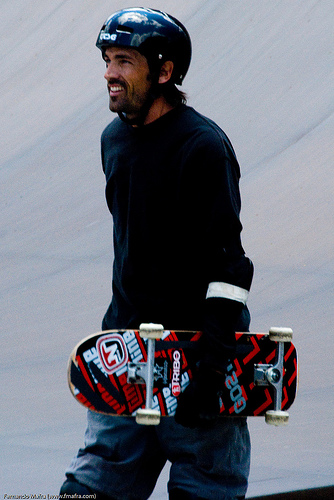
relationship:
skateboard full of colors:
[69, 322, 297, 425] [68, 330, 296, 416]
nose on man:
[104, 60, 121, 82] [59, 6, 255, 498]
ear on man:
[160, 60, 174, 85] [59, 6, 255, 498]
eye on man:
[118, 58, 134, 66] [59, 6, 255, 498]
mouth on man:
[107, 82, 126, 97] [59, 6, 255, 498]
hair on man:
[161, 81, 188, 108] [59, 6, 255, 498]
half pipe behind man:
[1, 2, 333, 499] [59, 6, 255, 498]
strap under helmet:
[105, 65, 161, 128] [96, 7, 191, 125]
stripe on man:
[204, 279, 249, 304] [59, 6, 255, 498]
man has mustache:
[59, 6, 255, 498] [106, 77, 129, 96]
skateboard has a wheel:
[69, 322, 297, 425] [139, 324, 166, 340]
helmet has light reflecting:
[96, 7, 191, 125] [98, 7, 189, 49]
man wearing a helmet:
[59, 6, 255, 498] [96, 7, 191, 125]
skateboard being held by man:
[69, 322, 297, 425] [59, 6, 255, 498]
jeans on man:
[59, 410, 252, 498] [59, 6, 255, 498]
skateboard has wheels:
[69, 322, 297, 425] [135, 323, 293, 427]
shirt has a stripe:
[101, 102, 254, 374] [204, 279, 249, 304]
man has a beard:
[59, 6, 255, 498] [109, 87, 149, 114]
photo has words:
[0, 0, 334, 499] [3, 492, 98, 499]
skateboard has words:
[69, 322, 297, 425] [69, 330, 248, 416]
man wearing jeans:
[59, 6, 255, 498] [59, 410, 252, 498]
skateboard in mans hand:
[69, 322, 297, 425] [177, 367, 223, 430]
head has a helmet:
[102, 45, 176, 113] [96, 7, 191, 125]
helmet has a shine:
[96, 7, 191, 125] [96, 6, 192, 51]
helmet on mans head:
[96, 7, 191, 125] [102, 45, 176, 113]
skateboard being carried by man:
[69, 322, 297, 425] [59, 6, 255, 498]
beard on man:
[109, 87, 149, 114] [59, 6, 255, 498]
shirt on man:
[101, 102, 254, 374] [59, 6, 255, 498]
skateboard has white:
[69, 322, 297, 425] [68, 322, 294, 427]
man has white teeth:
[59, 6, 255, 498] [108, 84, 124, 92]